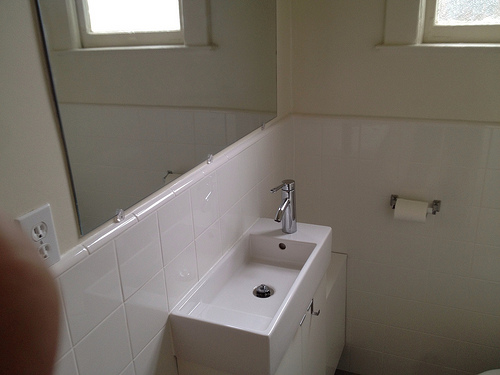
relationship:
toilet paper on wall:
[393, 197, 429, 223] [293, 114, 499, 374]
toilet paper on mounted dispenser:
[393, 197, 429, 223] [389, 194, 441, 216]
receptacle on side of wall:
[321, 249, 347, 365] [293, 114, 499, 374]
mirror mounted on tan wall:
[35, 1, 277, 234] [1, 1, 291, 274]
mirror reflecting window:
[35, 1, 277, 234] [85, 3, 180, 38]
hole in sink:
[277, 241, 286, 249] [177, 216, 332, 371]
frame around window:
[377, 2, 499, 59] [433, 1, 500, 26]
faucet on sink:
[269, 179, 298, 234] [177, 216, 332, 371]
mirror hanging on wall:
[35, 1, 277, 234] [1, 1, 291, 274]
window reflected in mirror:
[433, 1, 500, 26] [35, 1, 277, 234]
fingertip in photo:
[0, 210, 63, 374] [0, 0, 498, 373]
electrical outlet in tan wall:
[15, 205, 60, 269] [1, 1, 291, 274]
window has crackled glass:
[433, 1, 500, 26] [436, 0, 500, 26]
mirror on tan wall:
[35, 1, 277, 234] [1, 1, 291, 274]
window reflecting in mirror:
[85, 3, 180, 38] [35, 1, 277, 234]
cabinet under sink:
[270, 276, 338, 374] [177, 216, 332, 371]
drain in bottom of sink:
[252, 284, 275, 297] [177, 216, 332, 371]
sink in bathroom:
[177, 216, 332, 371] [1, 0, 500, 374]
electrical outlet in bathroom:
[15, 205, 60, 269] [1, 0, 500, 374]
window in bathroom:
[433, 1, 500, 26] [1, 0, 500, 374]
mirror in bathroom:
[35, 1, 277, 234] [1, 0, 500, 374]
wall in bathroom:
[293, 114, 499, 374] [1, 0, 500, 374]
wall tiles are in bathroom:
[33, 116, 499, 374] [1, 0, 500, 374]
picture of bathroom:
[0, 0, 498, 373] [1, 0, 500, 374]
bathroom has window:
[1, 0, 500, 374] [433, 1, 500, 26]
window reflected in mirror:
[85, 3, 180, 38] [35, 1, 277, 234]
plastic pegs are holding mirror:
[112, 120, 266, 219] [35, 1, 277, 234]